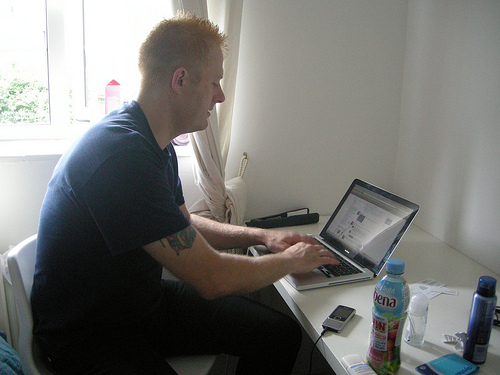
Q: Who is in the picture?
A: A man.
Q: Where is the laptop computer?
A: On the desk.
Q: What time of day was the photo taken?
A: Daytime.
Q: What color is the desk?
A: White.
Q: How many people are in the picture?
A: One.